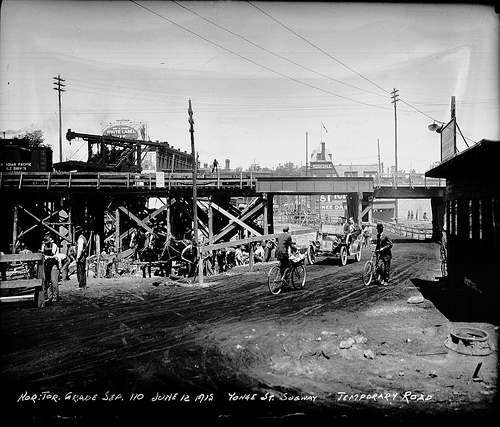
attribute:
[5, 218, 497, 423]
road — muddy